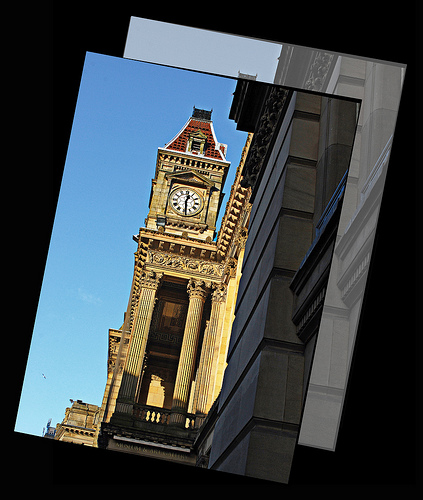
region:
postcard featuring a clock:
[9, 46, 368, 490]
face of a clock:
[162, 182, 206, 219]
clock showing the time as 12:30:
[165, 182, 206, 218]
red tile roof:
[153, 104, 233, 170]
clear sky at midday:
[11, 47, 260, 444]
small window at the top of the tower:
[185, 127, 205, 155]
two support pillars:
[111, 262, 214, 436]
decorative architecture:
[134, 190, 268, 286]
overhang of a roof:
[222, 72, 277, 139]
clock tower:
[140, 98, 235, 249]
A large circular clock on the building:
[161, 183, 209, 219]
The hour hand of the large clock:
[183, 194, 192, 202]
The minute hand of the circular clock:
[178, 203, 199, 218]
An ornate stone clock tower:
[113, 101, 262, 464]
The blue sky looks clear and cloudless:
[71, 142, 122, 242]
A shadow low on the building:
[94, 369, 148, 446]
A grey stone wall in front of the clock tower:
[248, 212, 305, 445]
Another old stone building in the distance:
[56, 399, 105, 449]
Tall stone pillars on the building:
[156, 277, 218, 441]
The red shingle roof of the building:
[160, 106, 236, 159]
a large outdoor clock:
[165, 182, 200, 222]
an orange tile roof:
[174, 108, 226, 158]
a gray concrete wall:
[223, 149, 290, 489]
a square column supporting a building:
[117, 267, 154, 427]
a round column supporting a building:
[166, 266, 195, 435]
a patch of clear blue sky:
[44, 104, 182, 392]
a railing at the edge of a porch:
[108, 397, 207, 445]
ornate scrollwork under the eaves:
[146, 256, 249, 294]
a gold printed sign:
[109, 436, 195, 467]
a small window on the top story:
[182, 131, 206, 151]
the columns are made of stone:
[181, 295, 199, 412]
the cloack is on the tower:
[163, 182, 214, 223]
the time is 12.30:
[170, 185, 212, 220]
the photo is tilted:
[49, 159, 368, 495]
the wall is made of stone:
[227, 223, 291, 416]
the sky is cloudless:
[73, 194, 109, 325]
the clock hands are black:
[166, 188, 205, 218]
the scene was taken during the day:
[56, 162, 348, 491]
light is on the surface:
[189, 275, 243, 369]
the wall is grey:
[227, 273, 283, 399]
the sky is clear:
[86, 72, 124, 139]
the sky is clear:
[58, 272, 127, 353]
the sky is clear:
[58, 278, 111, 399]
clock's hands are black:
[161, 185, 235, 232]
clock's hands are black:
[170, 181, 206, 229]